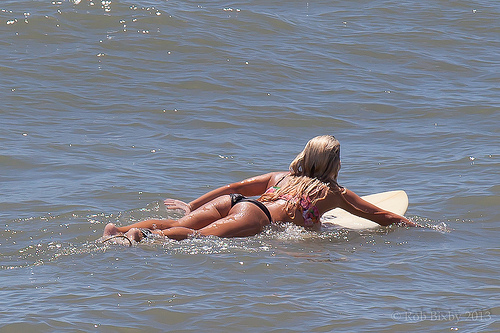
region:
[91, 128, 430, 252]
blond woman on a surfboard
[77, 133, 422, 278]
blond woman on a white surfboard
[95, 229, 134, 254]
rope to keep surfboard from separating from woman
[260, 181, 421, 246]
a white surfboard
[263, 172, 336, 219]
a wrinkled shirt on woman's back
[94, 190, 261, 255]
tanned legs partially submerged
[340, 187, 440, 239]
right arm paddling in water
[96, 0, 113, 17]
reflection of the sun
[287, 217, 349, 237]
shadow on the surfboard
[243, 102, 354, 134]
small wave in the water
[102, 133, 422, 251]
woman floating on water lying down on surfboard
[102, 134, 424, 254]
woman in two piece bikini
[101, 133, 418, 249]
woman lying down on white surfboard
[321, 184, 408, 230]
front tip of white surfboard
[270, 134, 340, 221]
blonde hair on the woman's head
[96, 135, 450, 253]
female surfer lying on a surfboard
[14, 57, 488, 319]
blonde haired woman floating on a surfboard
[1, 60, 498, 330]
young woman floating on calm water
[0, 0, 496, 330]
surfer floating on the water at the beach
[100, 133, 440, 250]
woman on top of surfboard at the beach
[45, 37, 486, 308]
the woman is surfing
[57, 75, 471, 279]
the woman is laying down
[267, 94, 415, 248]
the woman's hair is wet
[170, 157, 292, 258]
woman's bikini is black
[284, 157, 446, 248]
the surfboard is white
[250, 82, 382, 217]
woman's hair is blonde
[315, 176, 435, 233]
woman's arm is in water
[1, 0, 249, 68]
sun shining on water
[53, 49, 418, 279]
sun is shining on woman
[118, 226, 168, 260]
cord attached to woman's ankle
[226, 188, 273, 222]
Black Bikini Bottom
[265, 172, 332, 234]
Floral Pink Bikini Top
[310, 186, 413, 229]
White Surfboard in Water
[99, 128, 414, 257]
Blonde woman on surfboard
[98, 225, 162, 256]
Ankle tie for surf board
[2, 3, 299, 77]
Start of ocean wave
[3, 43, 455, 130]
Blue ocean water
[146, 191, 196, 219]
Hand paddling in ocean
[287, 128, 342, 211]
Long blonde hair that is wet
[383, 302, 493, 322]
Watermark for Rob Bixby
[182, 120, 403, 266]
girl paddling in the water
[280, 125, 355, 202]
blonde hair on girl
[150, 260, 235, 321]
ripples in th water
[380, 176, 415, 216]
surfboard under the girl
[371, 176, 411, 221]
white board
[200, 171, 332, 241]
bathing suit of girl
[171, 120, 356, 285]
girl in the water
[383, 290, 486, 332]
name in bottom right corner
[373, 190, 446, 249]
right arm of girl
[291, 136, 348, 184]
wet hair of the girl